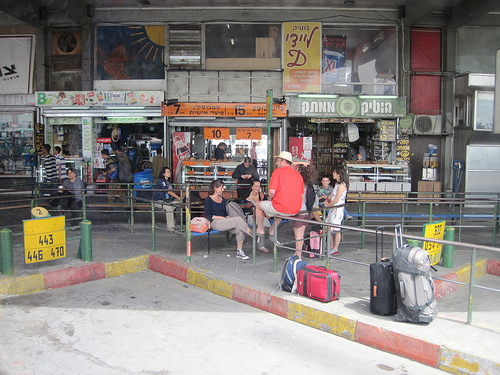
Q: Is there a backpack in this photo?
A: Yes, there is a backpack.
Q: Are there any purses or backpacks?
A: Yes, there is a backpack.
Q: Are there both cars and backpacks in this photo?
A: No, there is a backpack but no cars.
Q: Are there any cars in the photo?
A: No, there are no cars.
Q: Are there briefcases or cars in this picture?
A: No, there are no cars or briefcases.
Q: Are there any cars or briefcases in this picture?
A: No, there are no cars or briefcases.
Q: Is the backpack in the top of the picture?
A: No, the backpack is in the bottom of the image.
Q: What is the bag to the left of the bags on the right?
A: The bag is a backpack.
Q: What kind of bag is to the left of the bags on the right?
A: The bag is a backpack.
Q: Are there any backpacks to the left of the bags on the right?
A: Yes, there is a backpack to the left of the bags.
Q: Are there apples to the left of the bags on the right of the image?
A: No, there is a backpack to the left of the bags.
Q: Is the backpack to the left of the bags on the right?
A: Yes, the backpack is to the left of the bags.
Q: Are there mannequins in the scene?
A: No, there are no mannequins.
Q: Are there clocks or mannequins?
A: No, there are no mannequins or clocks.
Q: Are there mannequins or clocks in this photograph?
A: No, there are no mannequins or clocks.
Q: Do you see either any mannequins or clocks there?
A: No, there are no mannequins or clocks.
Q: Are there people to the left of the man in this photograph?
A: Yes, there is a person to the left of the man.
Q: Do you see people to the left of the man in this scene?
A: Yes, there is a person to the left of the man.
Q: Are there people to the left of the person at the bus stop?
A: Yes, there is a person to the left of the man.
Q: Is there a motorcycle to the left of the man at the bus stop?
A: No, there is a person to the left of the man.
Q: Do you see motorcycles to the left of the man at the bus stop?
A: No, there is a person to the left of the man.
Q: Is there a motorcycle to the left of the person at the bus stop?
A: No, there is a person to the left of the man.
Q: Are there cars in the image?
A: No, there are no cars.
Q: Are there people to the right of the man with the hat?
A: Yes, there is a person to the right of the man.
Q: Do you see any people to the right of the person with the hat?
A: Yes, there is a person to the right of the man.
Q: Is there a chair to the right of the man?
A: No, there is a person to the right of the man.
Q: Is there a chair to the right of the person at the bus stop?
A: No, there is a person to the right of the man.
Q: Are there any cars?
A: No, there are no cars.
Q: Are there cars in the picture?
A: No, there are no cars.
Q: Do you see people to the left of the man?
A: Yes, there is a person to the left of the man.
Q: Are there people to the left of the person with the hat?
A: Yes, there is a person to the left of the man.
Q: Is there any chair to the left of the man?
A: No, there is a person to the left of the man.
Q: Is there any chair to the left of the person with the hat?
A: No, there is a person to the left of the man.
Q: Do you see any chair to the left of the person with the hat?
A: No, there is a person to the left of the man.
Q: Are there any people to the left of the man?
A: Yes, there is a person to the left of the man.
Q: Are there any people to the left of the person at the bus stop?
A: Yes, there is a person to the left of the man.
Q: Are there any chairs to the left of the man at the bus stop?
A: No, there is a person to the left of the man.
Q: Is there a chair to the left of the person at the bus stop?
A: No, there is a person to the left of the man.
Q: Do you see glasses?
A: No, there are no glasses.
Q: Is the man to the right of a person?
A: Yes, the man is to the right of a person.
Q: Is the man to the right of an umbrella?
A: No, the man is to the right of a person.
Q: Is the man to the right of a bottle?
A: No, the man is to the right of a person.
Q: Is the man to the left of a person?
A: Yes, the man is to the left of a person.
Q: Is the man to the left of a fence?
A: No, the man is to the left of a person.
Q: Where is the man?
A: The man is at the bus stop.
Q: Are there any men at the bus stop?
A: Yes, there is a man at the bus stop.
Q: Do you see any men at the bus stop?
A: Yes, there is a man at the bus stop.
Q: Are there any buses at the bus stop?
A: No, there is a man at the bus stop.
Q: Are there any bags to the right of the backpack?
A: Yes, there are bags to the right of the backpack.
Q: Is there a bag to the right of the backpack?
A: Yes, there are bags to the right of the backpack.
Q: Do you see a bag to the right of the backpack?
A: Yes, there are bags to the right of the backpack.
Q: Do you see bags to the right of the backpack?
A: Yes, there are bags to the right of the backpack.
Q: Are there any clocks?
A: No, there are no clocks.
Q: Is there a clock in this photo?
A: No, there are no clocks.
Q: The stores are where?
A: The stores are at the bus stop.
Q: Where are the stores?
A: The stores are at the bus stop.